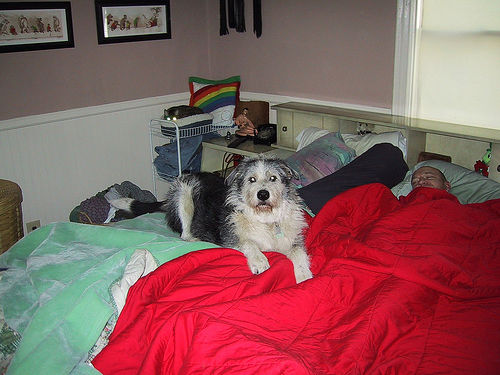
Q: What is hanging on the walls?
A: Painting.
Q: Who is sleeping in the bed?
A: A man.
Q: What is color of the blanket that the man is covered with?
A: Red.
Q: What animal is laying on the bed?
A: A dog.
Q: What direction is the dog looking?
A: Forward.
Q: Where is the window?
A: In the top right corner of the picture.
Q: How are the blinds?
A: Closed.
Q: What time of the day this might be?
A: Morning.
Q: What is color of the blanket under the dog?
A: Green.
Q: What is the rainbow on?
A: Pillow.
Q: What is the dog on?
A: A bed.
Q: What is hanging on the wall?
A: Two pictures.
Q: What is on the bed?
A: A black pillow.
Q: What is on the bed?
A: A white and black dog.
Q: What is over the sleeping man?
A: A red blanket.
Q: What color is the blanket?
A: Red.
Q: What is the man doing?
A: Sleeping.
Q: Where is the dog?
A: On the bed.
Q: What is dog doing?
A: Lying down.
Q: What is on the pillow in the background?
A: A rainbow.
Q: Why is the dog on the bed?
A: To rest.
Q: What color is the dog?
A: Black and white.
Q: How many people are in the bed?
A: One.